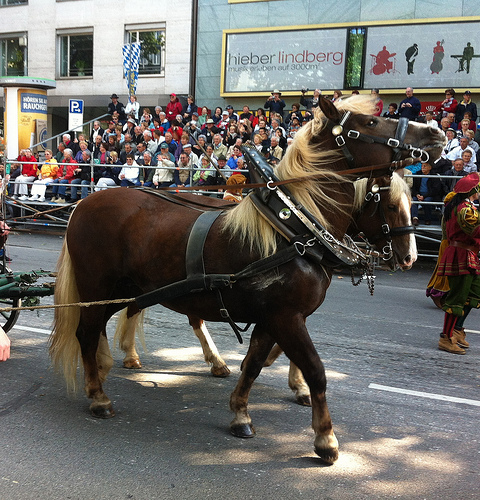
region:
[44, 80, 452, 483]
brown horses with blond manes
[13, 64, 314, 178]
a crowd of spectators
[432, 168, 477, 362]
renaissance man wearing construction boots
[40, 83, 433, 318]
black bridle attached to a horse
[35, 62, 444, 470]
brown horse trotting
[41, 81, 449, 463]
a brown horse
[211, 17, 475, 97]
an advertisement attached to a building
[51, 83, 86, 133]
a blue and white parking sign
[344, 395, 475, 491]
sunlight on black asphalt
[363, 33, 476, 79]
a picture of musicians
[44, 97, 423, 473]
two horses walking down the street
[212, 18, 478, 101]
a sign for a store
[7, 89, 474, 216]
a crowd in the streets watching a parade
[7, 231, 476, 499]
the street the animals are walking on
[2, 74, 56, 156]
the sign tower next to the people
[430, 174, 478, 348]
a person dressed up in costume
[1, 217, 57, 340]
a cart attached to the horses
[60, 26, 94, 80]
a window for the building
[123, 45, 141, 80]
a flag hanging on the pole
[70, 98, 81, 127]
a street sign by the crowd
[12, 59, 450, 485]
Two horses drawing a cart in a parade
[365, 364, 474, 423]
A white line painted on the street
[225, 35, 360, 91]
A sign that says heiber lindberg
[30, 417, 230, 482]
A gray asphalt road surface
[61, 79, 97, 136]
A sign indicating where to park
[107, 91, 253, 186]
The crowd watching the parade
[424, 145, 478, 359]
A costumed parade participant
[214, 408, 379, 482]
Two hooves on a brown horse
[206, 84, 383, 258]
The horse's mane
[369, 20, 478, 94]
A sign showing musical instruments being played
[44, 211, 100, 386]
Tail on a horse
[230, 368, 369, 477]
Hooves on a horse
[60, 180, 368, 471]
Brown horse walking on a street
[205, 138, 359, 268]
Black bridle on a horse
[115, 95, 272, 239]
Crowd watching horses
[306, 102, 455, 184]
Head on a horse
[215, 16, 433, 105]
Window on a building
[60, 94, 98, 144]
Parking sign by a crowd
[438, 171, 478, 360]
Person in a colorful dress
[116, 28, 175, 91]
Blue and white flag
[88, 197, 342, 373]
The horse is brown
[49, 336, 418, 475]
The horse is walking on the road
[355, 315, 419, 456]
The road is gray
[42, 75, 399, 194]
There are people in the stands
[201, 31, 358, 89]
The sign says hieber lindberg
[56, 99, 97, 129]
This sign is blue and white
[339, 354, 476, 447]
The road has lines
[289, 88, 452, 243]
The horse has reigns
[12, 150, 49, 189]
This person has a red coat on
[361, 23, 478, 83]
The sign has people playing instruments